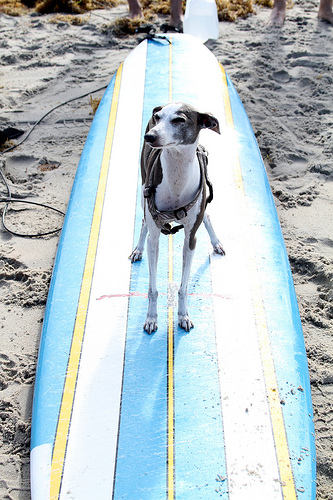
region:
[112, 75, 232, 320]
Dog on a surfboard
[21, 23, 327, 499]
White, blue and yellow surfboard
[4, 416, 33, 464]
Small dips in the sand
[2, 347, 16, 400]
Small dips in the sand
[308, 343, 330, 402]
Small dips in the sand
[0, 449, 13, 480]
Small dips in the sand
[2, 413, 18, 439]
Small dips in the sand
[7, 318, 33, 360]
Small dips in the sand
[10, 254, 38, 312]
Small dips in the sand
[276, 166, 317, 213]
Small dips in the sand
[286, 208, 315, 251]
Small dips in the sand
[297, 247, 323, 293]
Small dips in the sand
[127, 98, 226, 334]
black and white dog on surfboard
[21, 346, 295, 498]
blue yellow black and white stripes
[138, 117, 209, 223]
dog's clothing of brown color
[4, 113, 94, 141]
tire tracks in sand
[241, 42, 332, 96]
many foot prints in sand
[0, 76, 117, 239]
long cord going from trees to beach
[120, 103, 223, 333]
greyhound standing on surfboard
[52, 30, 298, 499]
yellow stripes on the surfboard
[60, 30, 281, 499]
white stripes on the surfboard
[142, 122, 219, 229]
harness on the greyhound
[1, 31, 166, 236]
black cord attached to surfboard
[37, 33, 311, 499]
blue stripes on the surfboard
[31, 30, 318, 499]
surfboard laying on the sand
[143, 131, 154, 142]
black nose of the dog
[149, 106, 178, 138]
white spot on dog's face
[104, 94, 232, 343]
a dog looking at the camera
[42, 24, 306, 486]
a blue, white and yellow surfboard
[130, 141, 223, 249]
a vest on a dog's back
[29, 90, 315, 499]
dog standing on a surfboard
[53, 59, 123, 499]
yellow and white lines on surfboard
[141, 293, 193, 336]
front paws of a dog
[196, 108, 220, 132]
floppy left ear of a dog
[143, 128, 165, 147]
wet black nose and closed muzzle of dog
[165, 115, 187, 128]
dark black left eye of dog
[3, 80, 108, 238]
surfboard safety tether cord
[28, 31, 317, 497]
dog standing on blue and yellow striped surfboard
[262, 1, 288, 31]
sand covered foot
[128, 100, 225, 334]
black and white dog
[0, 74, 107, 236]
cord attached to surfboard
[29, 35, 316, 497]
blue, yellow, and white striped surfboard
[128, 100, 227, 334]
dog wearing collar and harness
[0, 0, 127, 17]
dead brown seaweed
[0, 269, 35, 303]
foot print in the sand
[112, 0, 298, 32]
feet standing near brown seaweed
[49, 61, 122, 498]
yellow stripe on a surfboard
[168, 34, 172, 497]
yellow stripe on a surfboard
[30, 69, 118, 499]
blue stripe on a surfboard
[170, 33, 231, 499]
blue stripe on a surfboard